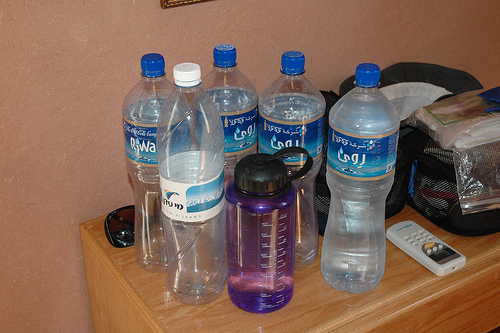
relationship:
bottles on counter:
[118, 53, 392, 303] [77, 231, 146, 332]